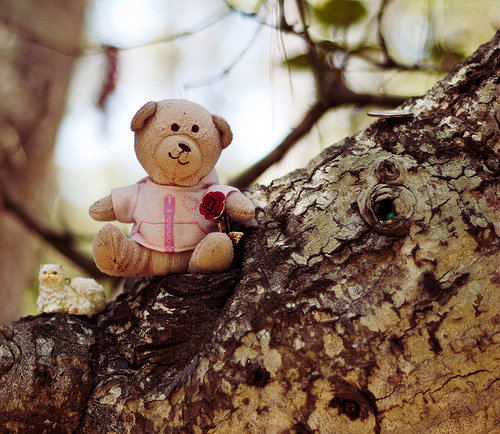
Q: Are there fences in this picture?
A: No, there are no fences.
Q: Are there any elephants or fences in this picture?
A: No, there are no fences or elephants.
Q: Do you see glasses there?
A: No, there are no glasses.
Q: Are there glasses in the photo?
A: No, there are no glasses.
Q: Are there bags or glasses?
A: No, there are no glasses or bags.